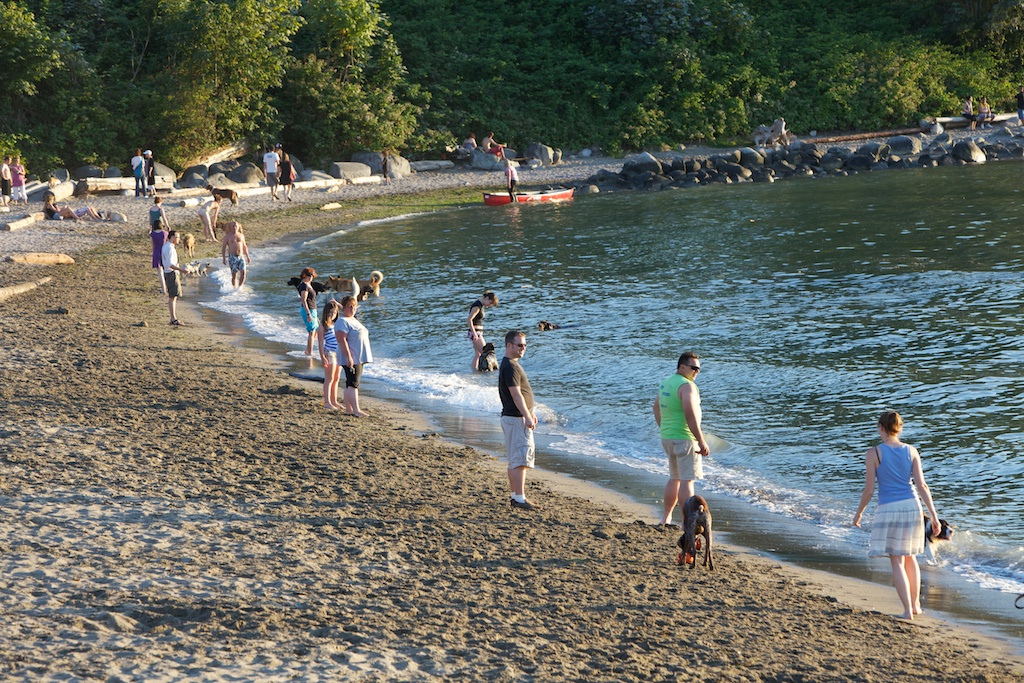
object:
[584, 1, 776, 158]
tree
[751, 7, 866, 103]
leaves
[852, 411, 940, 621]
people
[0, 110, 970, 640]
outdoors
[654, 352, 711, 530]
people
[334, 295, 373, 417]
people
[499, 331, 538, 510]
people